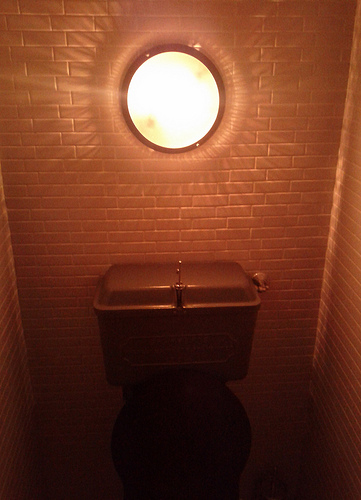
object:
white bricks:
[52, 56, 92, 150]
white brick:
[151, 196, 193, 206]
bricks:
[221, 185, 276, 213]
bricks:
[269, 113, 326, 150]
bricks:
[132, 201, 196, 236]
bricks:
[22, 103, 72, 141]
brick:
[21, 31, 66, 46]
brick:
[13, 77, 56, 92]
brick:
[16, 106, 59, 119]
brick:
[19, 132, 60, 146]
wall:
[0, 17, 356, 306]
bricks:
[270, 116, 322, 218]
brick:
[280, 269, 325, 281]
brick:
[306, 258, 326, 268]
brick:
[295, 233, 329, 249]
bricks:
[267, 59, 314, 79]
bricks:
[259, 43, 302, 65]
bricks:
[273, 28, 319, 45]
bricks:
[233, 30, 276, 48]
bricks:
[259, 13, 305, 35]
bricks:
[229, 216, 297, 239]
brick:
[99, 17, 149, 38]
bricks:
[267, 262, 317, 313]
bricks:
[19, 24, 76, 90]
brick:
[218, 158, 254, 169]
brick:
[232, 140, 268, 154]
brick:
[255, 129, 294, 144]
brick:
[269, 114, 306, 128]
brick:
[270, 90, 309, 102]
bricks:
[249, 360, 304, 382]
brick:
[25, 61, 68, 74]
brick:
[29, 89, 72, 102]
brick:
[74, 144, 112, 161]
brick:
[268, 143, 305, 155]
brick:
[274, 62, 312, 72]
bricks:
[27, 86, 74, 108]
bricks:
[235, 222, 330, 259]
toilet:
[88, 255, 270, 498]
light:
[126, 43, 226, 152]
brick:
[266, 192, 299, 206]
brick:
[227, 168, 265, 181]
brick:
[180, 206, 214, 220]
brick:
[67, 231, 105, 244]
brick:
[52, 304, 90, 318]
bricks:
[245, 31, 315, 63]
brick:
[264, 278, 293, 288]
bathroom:
[1, 1, 360, 497]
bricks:
[0, 0, 360, 497]